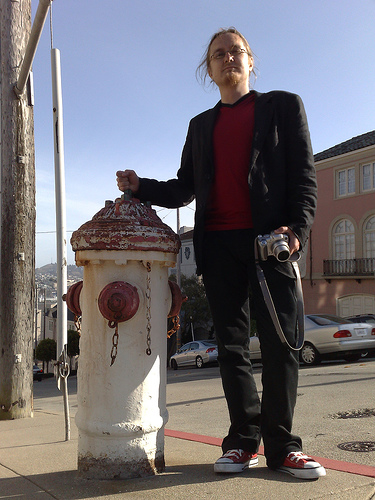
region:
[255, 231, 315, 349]
A nice digital camera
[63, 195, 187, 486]
an old, red and white fire hydrant.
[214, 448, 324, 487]
a pair of red tennis shoes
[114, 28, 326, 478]
A man with a goatee and glasses wearing a red shirt and a black jacket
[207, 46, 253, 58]
eye glasses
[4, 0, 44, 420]
a large telephone pole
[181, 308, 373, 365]
Two silver cars on the other side of the street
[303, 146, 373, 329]
A pink house on the other side of the street.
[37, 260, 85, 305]
a steep hill in the background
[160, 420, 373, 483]
a red, NO PARKING stripe painted on the curb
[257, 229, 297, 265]
The camera in the guy's hand.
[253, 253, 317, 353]
The strap attached to the camera.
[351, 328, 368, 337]
The license plate of the car parked on the right.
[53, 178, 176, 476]
The hydrant that the guy is touching.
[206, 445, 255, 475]
The left sneaker the guy is wearing.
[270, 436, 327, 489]
The right sneaker the guy is wearing.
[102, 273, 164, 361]
The chains hanging from the hydrant.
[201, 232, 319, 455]
The black pants the man is wearing.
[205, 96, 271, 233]
The burgundy shirt the guy is wearing.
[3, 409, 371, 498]
The sidewalk where the man is standing.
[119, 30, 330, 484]
a man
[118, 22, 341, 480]
a man stands on a sidewalk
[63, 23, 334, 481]
the man has his fist on a large fire hydrant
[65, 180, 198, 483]
the fire hydrant is white and red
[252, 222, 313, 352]
the man holds a camera in his left hand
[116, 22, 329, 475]
a man is wearing red and white sneakers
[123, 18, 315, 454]
the man is wearing glasses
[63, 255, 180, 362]
chains are hanging on the fire hydrant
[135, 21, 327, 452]
the man is wearing black pants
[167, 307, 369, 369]
cars are parked along the road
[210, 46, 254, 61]
Man is wearing glasses.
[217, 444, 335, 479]
Man is wearing red and white shoes.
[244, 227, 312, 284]
Man is holding digital camera.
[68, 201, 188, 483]
Red and white fire hydrant.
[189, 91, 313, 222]
Man wearing black jacket.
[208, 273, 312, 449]
Man wearing black pants.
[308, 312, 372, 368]
Silver colored car.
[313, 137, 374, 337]
Pink colored building in background.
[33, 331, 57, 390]
Green colored tree in background.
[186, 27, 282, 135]
Man with blonde hair and goatee.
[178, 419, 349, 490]
red and white converse sneakers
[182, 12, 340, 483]
a man wearing red and white converse sneakers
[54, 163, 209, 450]
a red and white fire hydrant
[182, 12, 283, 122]
a man wearing glasses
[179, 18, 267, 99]
a man with his hair up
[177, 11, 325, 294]
a man holding a camera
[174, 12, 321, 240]
a man wearing a red shirt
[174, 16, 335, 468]
a man wearing pants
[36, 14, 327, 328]
a man holding a fire hydrant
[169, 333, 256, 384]
a silver car